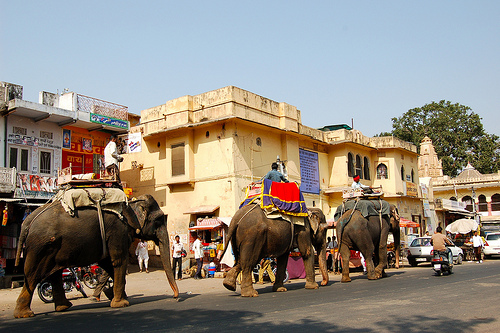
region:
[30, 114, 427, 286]
three elephants in a parade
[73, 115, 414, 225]
three people riding elephants on the street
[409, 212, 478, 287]
a man riding a motorcycle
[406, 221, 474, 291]
a white station wagon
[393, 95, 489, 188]
a deciduous tree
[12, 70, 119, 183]
a building under construction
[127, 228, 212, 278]
three people standing in the street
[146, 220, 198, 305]
an elephant's trunk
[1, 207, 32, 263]
the tail of an elephant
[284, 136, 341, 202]
a purple sign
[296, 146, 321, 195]
purple-blue sign with black writing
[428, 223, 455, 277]
man riding a scooter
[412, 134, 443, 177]
cylindrical tower made of stone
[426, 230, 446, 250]
a peach colored tshirt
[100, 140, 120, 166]
white button down shirt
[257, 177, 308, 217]
multi-colored blanket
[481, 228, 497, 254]
rear end of a white hatch back car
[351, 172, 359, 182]
bright neon red headband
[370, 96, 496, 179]
bushy green top of a tree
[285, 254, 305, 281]
medium shade purple blanket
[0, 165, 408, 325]
three elephants walking on a roadway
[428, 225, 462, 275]
a man riding a scooter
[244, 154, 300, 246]
a man riding a elephant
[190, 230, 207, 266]
a man wearing a white shirt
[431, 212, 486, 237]
a tan and white umbrella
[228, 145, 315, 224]
a purple, red and yellow blanket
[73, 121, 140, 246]
a man standing up on a elephant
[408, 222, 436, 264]
a small white car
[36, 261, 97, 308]
a motorcycle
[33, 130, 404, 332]
three people riding elephants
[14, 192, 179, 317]
Large grey elephant walking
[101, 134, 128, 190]
Man standing on an elephant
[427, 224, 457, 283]
Man riding a moped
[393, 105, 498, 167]
Large green tree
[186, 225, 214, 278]
Man standing at small market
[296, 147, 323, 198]
Sign portraying from building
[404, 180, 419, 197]
sign hanging from building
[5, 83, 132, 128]
Ledge overhang on roof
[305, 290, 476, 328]
long grey pavement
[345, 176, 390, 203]
Man setting in sattle on elephant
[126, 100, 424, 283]
a tan building alongside a road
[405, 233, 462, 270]
a white car on the road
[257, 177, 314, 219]
a red, blue, and gold decorative blanket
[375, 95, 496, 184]
a tree behind a building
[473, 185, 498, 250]
a chain link fence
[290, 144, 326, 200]
a sign posted on a building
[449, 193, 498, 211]
arched openings in a building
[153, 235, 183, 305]
an elephant's long trunk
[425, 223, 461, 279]
a man on a motorcycle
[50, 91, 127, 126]
a balcony on top of a roof